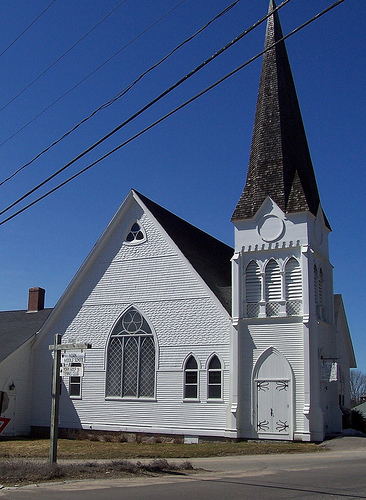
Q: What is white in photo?
A: Church is white.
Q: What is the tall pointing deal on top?
A: The steeple.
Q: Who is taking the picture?
A: A photographer.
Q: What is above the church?
A: Wires.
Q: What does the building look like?
A: A white church.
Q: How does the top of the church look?
A: Black.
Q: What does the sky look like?
A: The sky is clear blue.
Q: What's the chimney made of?
A: Red brick.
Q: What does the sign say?
A: The sign isn't legible.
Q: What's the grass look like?
A: The grass is dying.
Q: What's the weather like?
A: Clear and cool.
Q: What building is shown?
A: A church.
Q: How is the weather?
A: Clear and sunny,.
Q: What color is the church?
A: White.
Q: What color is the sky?
A: Blue.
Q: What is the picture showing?
A: A church.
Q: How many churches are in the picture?
A: One.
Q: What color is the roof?
A: Black.